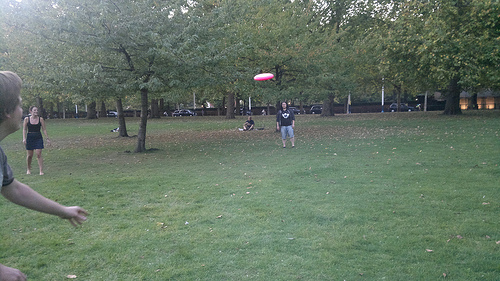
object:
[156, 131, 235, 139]
brown grass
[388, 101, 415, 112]
car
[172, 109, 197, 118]
car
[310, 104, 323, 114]
car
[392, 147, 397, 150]
leaves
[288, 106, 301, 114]
parked cars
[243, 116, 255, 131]
man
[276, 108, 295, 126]
shirt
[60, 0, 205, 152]
leafy tree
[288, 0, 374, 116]
leafy tree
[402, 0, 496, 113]
leafy tree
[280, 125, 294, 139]
jeans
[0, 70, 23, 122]
hair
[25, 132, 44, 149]
skirt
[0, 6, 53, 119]
tree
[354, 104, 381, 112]
wall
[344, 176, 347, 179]
leaves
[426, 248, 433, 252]
leaves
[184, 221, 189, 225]
leaves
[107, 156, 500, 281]
grass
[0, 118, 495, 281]
field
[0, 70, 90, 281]
man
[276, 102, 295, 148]
man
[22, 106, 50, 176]
female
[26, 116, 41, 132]
black shirt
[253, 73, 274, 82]
frisbee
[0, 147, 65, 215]
arm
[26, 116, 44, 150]
dress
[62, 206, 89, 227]
hand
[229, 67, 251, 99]
air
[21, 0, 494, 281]
park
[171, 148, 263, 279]
ground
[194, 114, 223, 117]
street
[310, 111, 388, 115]
street